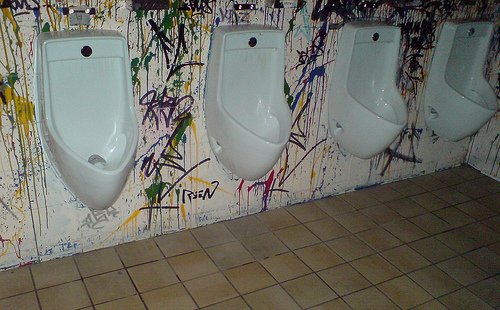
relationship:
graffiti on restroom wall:
[134, 25, 222, 222] [127, 22, 224, 210]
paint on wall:
[132, 14, 204, 222] [7, 29, 398, 176]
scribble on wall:
[116, 47, 207, 208] [135, 72, 211, 218]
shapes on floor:
[269, 208, 478, 300] [288, 203, 470, 303]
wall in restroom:
[18, 31, 478, 183] [9, 28, 497, 301]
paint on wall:
[132, 14, 204, 222] [6, 10, 459, 179]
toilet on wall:
[23, 20, 153, 231] [6, 10, 459, 179]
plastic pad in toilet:
[75, 151, 112, 177] [23, 20, 153, 231]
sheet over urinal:
[56, 1, 101, 30] [14, 0, 151, 224]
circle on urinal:
[78, 42, 91, 55] [29, 28, 143, 227]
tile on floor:
[120, 232, 250, 306] [160, 254, 239, 306]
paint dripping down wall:
[132, 14, 204, 222] [6, 10, 459, 179]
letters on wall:
[170, 176, 225, 206] [12, 15, 488, 181]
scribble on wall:
[116, 47, 207, 208] [10, 10, 489, 273]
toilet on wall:
[23, 20, 153, 231] [7, 6, 486, 240]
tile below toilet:
[120, 232, 250, 306] [195, 18, 300, 210]